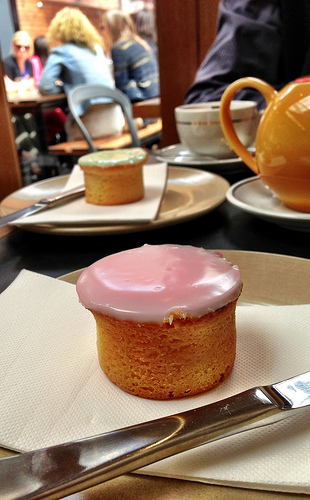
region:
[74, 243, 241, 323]
Pink icing on pastry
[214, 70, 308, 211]
Orange kettle on round white plate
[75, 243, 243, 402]
Pastry on white napkin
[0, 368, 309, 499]
Knife on white napkin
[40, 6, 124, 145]
Woman wearing blue jacket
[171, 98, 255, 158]
Mug on white plate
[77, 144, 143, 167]
Green icing on pastry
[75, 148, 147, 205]
Pastry on top of white napkin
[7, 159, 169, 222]
White napkin under plate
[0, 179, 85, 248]
Knife next to napkin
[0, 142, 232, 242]
The plate is round.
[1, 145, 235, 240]
The plate has a napkin on it.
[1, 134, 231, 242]
The napkin is white.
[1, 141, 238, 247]
The cupcake is on the napkin.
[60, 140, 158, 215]
The cupcake is frosted.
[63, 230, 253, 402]
The cupcake is frosted.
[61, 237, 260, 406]
Pink frosting on a cupcake.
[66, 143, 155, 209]
Green frosting on a cupcake.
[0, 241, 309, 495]
The cupcake is on a napkin.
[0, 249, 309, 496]
The napkin is paper.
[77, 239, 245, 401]
cupcake with pink icing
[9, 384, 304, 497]
silver knife beside cupcake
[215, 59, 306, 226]
orange teapot on a saucer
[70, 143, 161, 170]
green icing on a cupcake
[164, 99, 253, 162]
coffee cup with a gold stripe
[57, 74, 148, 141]
back of an empty chair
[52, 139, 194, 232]
cupcake sitting on a plate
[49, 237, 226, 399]
cupcake sitting on a napkin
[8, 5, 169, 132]
people sitting at a table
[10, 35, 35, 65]
person wearing glasses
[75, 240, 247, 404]
Cupcake with pink frosting.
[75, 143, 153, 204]
Cupcake with yellow frosting.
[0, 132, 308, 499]
Two cupcakes on two light brown plates.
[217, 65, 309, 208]
Tan colored tea kettle.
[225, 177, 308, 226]
White saucer with a line for tea kettle.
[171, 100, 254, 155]
White cup with gold line.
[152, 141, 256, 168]
White saucer with gold line.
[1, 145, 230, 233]
Brown plate holding yellow frosted cupcake.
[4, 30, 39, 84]
Blonde woman wearing sunglasses.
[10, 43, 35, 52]
Sunglasses worn by blonde woman.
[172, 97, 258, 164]
white tea cup with gold trim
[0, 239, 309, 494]
cupcake on a plate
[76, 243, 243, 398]
cupcake with pink frosting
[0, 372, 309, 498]
silver butterknife on plate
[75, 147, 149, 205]
cupcake with yellow frosting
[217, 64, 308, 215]
orange tea pot on table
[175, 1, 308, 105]
arm of person sitting at table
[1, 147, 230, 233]
tan plate with yellow cupcake on top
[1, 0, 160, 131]
group of women sitting together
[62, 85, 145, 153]
gray backing of a chair